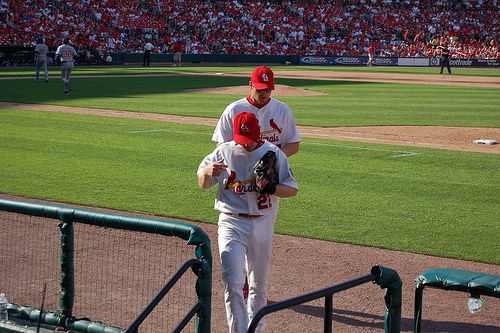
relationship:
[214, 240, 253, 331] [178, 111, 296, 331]
leg on player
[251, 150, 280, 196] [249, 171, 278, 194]
glove on hand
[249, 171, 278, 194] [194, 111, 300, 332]
hand on man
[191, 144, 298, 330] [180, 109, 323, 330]
uniform on player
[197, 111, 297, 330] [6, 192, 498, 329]
baseball player entering dugout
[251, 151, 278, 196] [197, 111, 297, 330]
glove on baseball player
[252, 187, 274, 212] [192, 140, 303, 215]
red 21 on white jersey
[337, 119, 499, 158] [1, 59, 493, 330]
base on field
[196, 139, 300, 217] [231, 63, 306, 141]
jersey on man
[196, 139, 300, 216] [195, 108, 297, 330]
jersey on man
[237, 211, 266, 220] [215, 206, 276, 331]
belt on pants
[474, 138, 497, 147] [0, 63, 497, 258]
base plate sitting on baseball field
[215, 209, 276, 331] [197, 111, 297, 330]
pants worn by baseball player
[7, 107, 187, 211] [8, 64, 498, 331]
grass on baseball field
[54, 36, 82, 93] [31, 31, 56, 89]
player with player